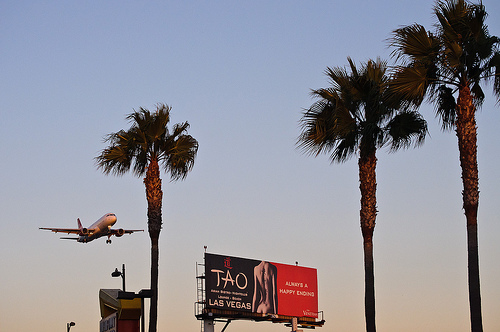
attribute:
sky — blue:
[1, 0, 488, 228]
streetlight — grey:
[109, 265, 126, 278]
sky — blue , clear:
[0, 0, 499, 330]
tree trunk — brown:
[454, 83, 485, 330]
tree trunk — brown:
[355, 155, 380, 329]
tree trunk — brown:
[140, 157, 164, 329]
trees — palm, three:
[260, 47, 470, 267]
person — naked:
[248, 256, 280, 318]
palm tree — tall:
[97, 95, 199, 330]